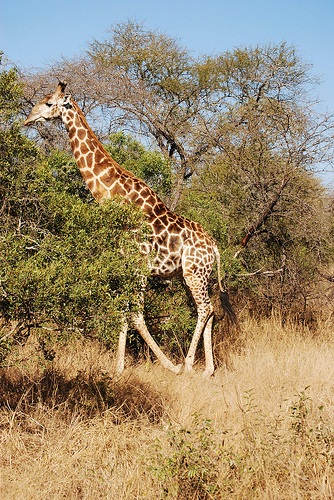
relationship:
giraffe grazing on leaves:
[18, 75, 232, 382] [2, 69, 22, 110]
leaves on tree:
[2, 69, 22, 110] [0, 51, 256, 370]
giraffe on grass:
[18, 75, 232, 382] [74, 439, 168, 497]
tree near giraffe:
[0, 51, 334, 370] [18, 75, 232, 382]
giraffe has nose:
[18, 75, 232, 382] [13, 104, 50, 129]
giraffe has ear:
[18, 75, 232, 382] [59, 90, 71, 106]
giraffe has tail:
[40, 87, 285, 354] [211, 238, 242, 335]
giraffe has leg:
[18, 75, 232, 382] [183, 276, 208, 375]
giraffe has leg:
[18, 75, 232, 382] [203, 313, 215, 378]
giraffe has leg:
[18, 75, 232, 382] [133, 281, 180, 378]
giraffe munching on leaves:
[18, 75, 232, 382] [0, 49, 143, 369]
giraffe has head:
[18, 75, 232, 382] [18, 78, 73, 129]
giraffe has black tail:
[18, 75, 232, 382] [217, 289, 241, 332]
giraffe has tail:
[18, 75, 232, 382] [209, 236, 237, 319]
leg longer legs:
[183, 276, 208, 375] [182, 249, 215, 374]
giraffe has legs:
[18, 75, 232, 382] [182, 249, 215, 374]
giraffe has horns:
[18, 75, 232, 382] [54, 77, 74, 93]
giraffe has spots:
[18, 75, 232, 382] [134, 199, 154, 214]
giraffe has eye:
[18, 75, 232, 382] [45, 100, 54, 106]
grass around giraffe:
[11, 374, 331, 498] [1, 49, 267, 320]